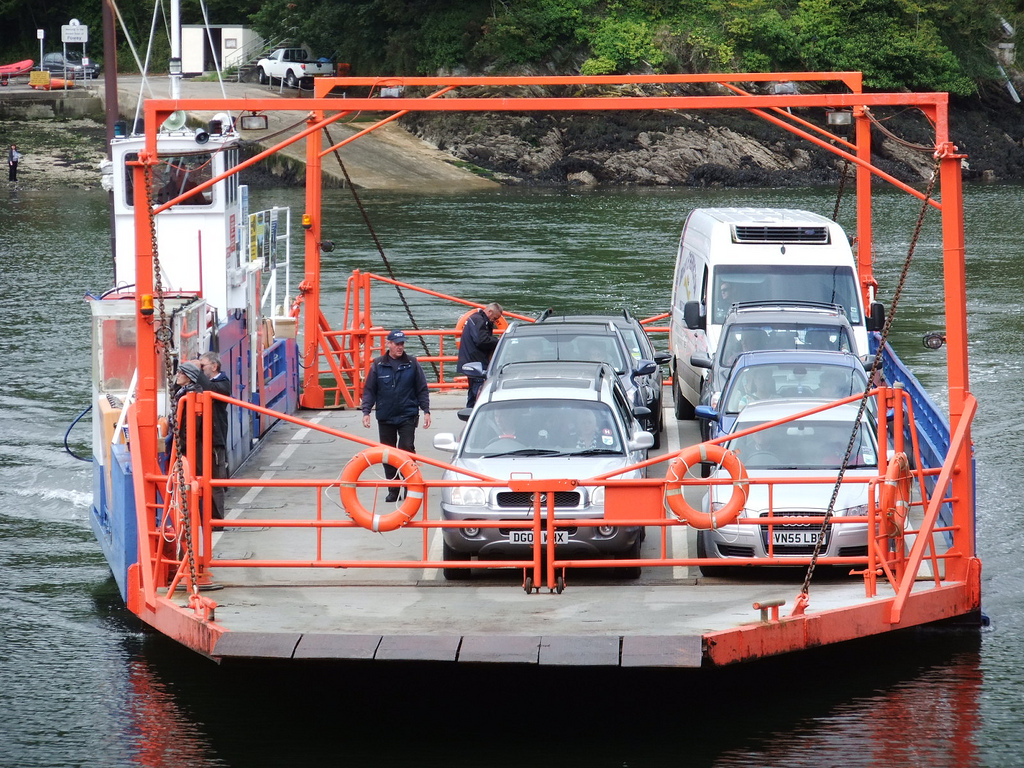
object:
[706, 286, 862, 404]
suv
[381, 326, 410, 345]
hat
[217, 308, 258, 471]
doors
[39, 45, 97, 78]
car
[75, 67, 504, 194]
ramp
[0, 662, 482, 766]
water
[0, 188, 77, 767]
water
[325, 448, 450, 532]
life preservers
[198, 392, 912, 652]
gate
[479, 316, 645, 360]
cars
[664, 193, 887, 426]
van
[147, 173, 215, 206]
window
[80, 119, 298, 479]
building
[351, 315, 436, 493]
man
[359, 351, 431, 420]
jacket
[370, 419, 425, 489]
pants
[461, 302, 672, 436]
vehicles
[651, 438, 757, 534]
safety donut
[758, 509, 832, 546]
license plate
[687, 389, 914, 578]
car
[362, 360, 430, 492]
uniform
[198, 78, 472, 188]
road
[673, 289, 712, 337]
mirror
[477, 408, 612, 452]
people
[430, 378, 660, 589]
car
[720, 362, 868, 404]
windshield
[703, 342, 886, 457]
car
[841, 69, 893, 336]
post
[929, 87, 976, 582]
post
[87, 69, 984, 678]
ferry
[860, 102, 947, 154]
rope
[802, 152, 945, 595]
rope